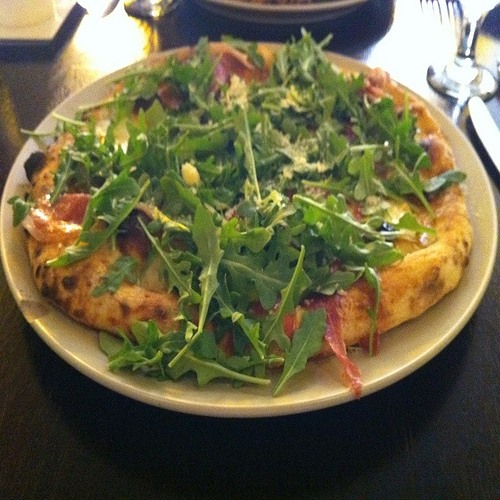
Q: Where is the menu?
A: There is no menu.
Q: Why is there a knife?
A: To cut food.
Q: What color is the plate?
A: White.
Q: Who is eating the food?
A: No one.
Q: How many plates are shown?
A: One.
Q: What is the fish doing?
A: There is no fish.